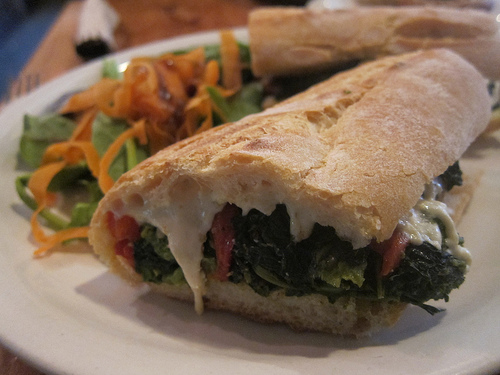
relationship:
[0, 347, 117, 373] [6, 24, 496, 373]
edge on plate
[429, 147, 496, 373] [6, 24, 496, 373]
side on plate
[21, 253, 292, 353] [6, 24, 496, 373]
inside on plate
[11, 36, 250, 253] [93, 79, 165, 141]
section has vegetables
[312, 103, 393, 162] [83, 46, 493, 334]
section on bread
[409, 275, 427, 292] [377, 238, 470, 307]
part on vegetable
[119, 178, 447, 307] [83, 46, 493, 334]
sauce on bread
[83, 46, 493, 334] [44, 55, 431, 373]
bread on a plate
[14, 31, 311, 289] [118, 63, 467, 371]
salad next to sandwich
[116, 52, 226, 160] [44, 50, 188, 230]
carrots on salad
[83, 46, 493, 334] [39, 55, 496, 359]
bread on plate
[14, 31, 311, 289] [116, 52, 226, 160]
salad with carrots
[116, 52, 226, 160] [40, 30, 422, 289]
carrots on a salad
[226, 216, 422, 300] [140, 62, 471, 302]
broccoli in a sandwich